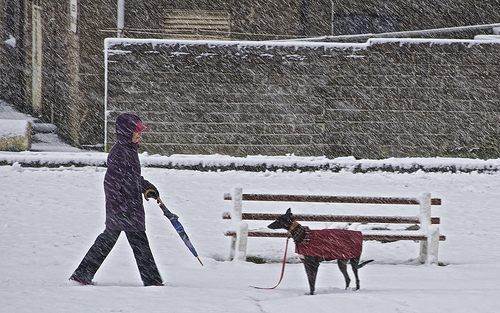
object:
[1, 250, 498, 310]
path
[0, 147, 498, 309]
snow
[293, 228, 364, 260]
sweater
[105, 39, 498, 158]
wall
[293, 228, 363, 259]
blanket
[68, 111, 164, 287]
boy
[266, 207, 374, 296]
dog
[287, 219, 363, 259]
outfit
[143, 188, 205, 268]
item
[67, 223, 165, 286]
pants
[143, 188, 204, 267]
umbrella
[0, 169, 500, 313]
ground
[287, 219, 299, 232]
collar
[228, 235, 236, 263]
back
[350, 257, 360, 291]
leg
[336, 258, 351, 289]
leg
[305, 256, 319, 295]
leg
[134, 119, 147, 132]
hat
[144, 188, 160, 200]
person's hand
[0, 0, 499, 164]
background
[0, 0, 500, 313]
air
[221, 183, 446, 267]
bench